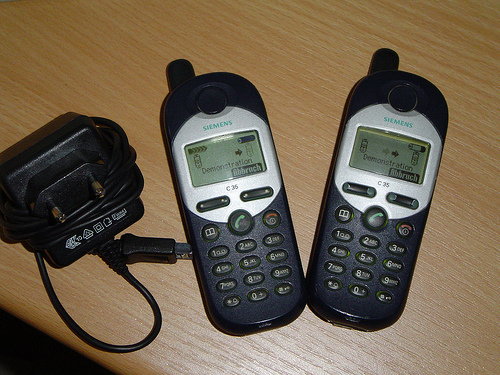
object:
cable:
[0, 111, 194, 354]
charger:
[0, 111, 190, 353]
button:
[207, 246, 228, 260]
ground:
[0, 0, 500, 375]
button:
[362, 206, 387, 231]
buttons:
[209, 261, 234, 278]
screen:
[349, 125, 430, 192]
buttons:
[341, 181, 376, 197]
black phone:
[156, 58, 306, 339]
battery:
[237, 135, 256, 144]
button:
[398, 223, 413, 239]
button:
[334, 206, 352, 223]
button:
[227, 212, 253, 233]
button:
[263, 210, 282, 227]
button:
[323, 279, 341, 291]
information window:
[183, 127, 268, 188]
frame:
[170, 105, 280, 225]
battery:
[408, 143, 426, 153]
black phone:
[303, 47, 450, 335]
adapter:
[0, 111, 194, 353]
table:
[1, 1, 500, 375]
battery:
[0, 109, 147, 268]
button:
[359, 233, 382, 248]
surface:
[0, 0, 500, 375]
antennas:
[163, 58, 197, 92]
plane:
[303, 46, 448, 331]